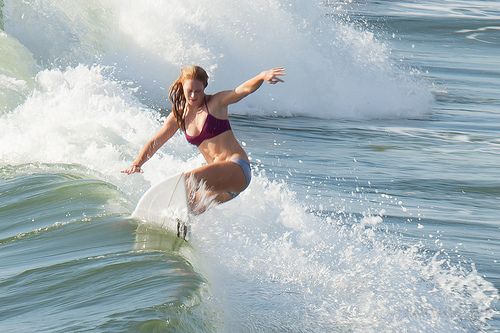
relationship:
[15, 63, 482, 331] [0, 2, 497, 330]
wave in ocean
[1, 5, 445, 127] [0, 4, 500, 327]
ocean spray from wave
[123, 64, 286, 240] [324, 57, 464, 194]
surfer in water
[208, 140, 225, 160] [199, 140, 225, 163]
abs ore on abs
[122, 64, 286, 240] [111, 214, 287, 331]
surfer on wave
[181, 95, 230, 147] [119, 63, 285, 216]
bikini top on surfer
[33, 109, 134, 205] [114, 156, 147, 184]
water splashing under woman's hand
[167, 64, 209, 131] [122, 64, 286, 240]
hair over surfer